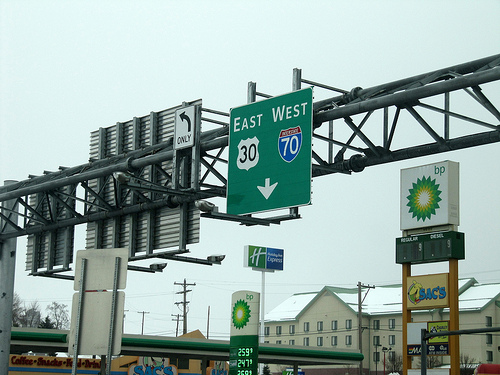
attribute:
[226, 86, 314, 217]
sign — large, green, square, hanging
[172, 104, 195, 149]
sign — white, black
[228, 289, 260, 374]
bp sign — green, yellow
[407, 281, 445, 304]
logo — smiling dog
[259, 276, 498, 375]
hotel — distant, large, beige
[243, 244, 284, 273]
sign — tall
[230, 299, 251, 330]
logo — green, sun shaped, yellow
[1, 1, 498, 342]
sky — gray overcast, light gray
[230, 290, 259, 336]
background — white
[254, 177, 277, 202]
down arrow — white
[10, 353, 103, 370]
letters — red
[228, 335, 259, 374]
background — green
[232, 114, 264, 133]
word — white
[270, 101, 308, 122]
word — white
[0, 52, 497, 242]
beam — metal